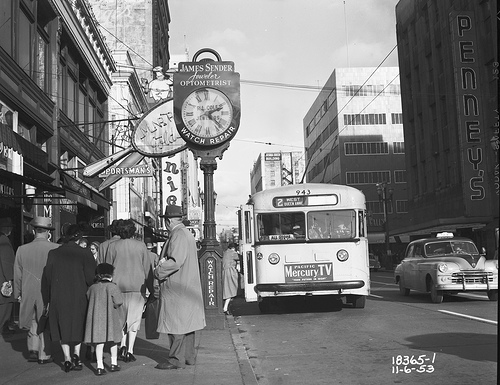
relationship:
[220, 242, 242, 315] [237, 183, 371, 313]
woman boarding bus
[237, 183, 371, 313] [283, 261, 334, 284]
bus has mercury tv ad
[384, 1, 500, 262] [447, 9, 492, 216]
building has penney's sign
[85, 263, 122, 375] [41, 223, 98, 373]
child near woman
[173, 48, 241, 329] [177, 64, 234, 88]
clock has ad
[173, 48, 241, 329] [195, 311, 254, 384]
clock on sidewalk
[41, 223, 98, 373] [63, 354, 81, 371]
woman wearing black shoes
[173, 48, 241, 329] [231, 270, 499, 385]
clock near street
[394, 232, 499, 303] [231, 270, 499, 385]
taxi cab on street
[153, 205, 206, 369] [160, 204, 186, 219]
man wearing hat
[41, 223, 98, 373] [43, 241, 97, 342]
woman wearing coat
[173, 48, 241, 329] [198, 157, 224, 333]
clock on pole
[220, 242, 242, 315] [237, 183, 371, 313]
woman getting on bus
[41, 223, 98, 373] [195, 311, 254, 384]
woman walking down sidewalk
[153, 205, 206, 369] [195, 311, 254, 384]
man on sidewalk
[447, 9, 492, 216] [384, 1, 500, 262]
penney's sign on building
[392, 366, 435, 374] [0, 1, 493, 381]
photo date on photo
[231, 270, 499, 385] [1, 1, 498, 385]
street in city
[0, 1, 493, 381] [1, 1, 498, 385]
photo of city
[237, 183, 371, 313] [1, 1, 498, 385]
bus in city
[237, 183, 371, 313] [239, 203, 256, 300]
bus has doors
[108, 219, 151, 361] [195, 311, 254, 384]
woman walking on sidewalk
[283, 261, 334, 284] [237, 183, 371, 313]
mercury tv ad on bus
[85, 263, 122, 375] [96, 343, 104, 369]
child wearing white tights